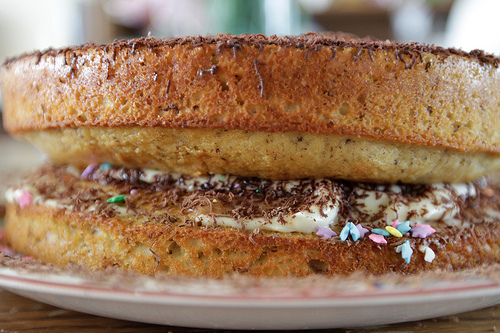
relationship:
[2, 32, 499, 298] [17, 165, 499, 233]
cake has whipped cream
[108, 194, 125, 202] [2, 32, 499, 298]
sprinkles are on a cake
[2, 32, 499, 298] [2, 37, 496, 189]
cake has a layer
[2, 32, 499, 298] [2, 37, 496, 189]
cake has layer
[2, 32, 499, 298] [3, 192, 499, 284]
cake has a bottom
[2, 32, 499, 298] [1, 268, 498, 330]
cake on plate